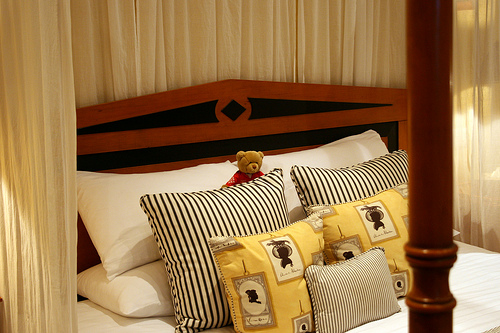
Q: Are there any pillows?
A: Yes, there is a pillow.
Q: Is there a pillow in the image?
A: Yes, there is a pillow.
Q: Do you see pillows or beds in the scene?
A: Yes, there is a pillow.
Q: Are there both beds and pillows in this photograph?
A: Yes, there are both a pillow and a bed.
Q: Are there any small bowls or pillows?
A: Yes, there is a small pillow.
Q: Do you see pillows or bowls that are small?
A: Yes, the pillow is small.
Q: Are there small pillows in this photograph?
A: Yes, there is a small pillow.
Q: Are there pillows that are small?
A: Yes, there is a small pillow.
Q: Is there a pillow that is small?
A: Yes, there is a pillow that is small.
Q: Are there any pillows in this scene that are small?
A: Yes, there is a pillow that is small.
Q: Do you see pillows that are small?
A: Yes, there is a pillow that is small.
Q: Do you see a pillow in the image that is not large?
A: Yes, there is a small pillow.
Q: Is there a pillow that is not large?
A: Yes, there is a small pillow.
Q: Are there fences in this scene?
A: No, there are no fences.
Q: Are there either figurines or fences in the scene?
A: No, there are no fences or figurines.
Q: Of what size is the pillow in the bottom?
A: The pillow is small.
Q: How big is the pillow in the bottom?
A: The pillow is small.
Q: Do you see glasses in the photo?
A: No, there are no glasses.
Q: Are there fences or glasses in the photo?
A: No, there are no glasses or fences.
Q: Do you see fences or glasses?
A: No, there are no glasses or fences.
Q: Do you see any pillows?
A: Yes, there is a pillow.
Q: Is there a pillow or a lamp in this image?
A: Yes, there is a pillow.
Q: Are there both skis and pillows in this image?
A: No, there is a pillow but no skis.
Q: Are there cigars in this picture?
A: No, there are no cigars.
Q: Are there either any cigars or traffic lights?
A: No, there are no cigars or traffic lights.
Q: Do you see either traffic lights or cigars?
A: No, there are no cigars or traffic lights.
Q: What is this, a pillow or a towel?
A: This is a pillow.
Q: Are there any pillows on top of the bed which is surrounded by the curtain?
A: Yes, there is a pillow on top of the bed.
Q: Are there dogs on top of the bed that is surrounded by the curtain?
A: No, there is a pillow on top of the bed.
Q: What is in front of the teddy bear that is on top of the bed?
A: The pillow is in front of the teddy bear.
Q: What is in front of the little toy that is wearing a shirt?
A: The pillow is in front of the teddy bear.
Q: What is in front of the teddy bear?
A: The pillow is in front of the teddy bear.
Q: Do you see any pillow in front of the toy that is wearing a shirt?
A: Yes, there is a pillow in front of the teddy bear.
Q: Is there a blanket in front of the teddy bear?
A: No, there is a pillow in front of the teddy bear.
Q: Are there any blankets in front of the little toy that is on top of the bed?
A: No, there is a pillow in front of the teddy bear.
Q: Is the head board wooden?
A: Yes, the head board is wooden.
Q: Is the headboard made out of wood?
A: Yes, the headboard is made of wood.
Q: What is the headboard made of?
A: The headboard is made of wood.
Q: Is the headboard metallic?
A: No, the headboard is wooden.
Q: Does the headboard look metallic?
A: No, the headboard is wooden.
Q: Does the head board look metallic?
A: No, the head board is wooden.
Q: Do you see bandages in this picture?
A: No, there are no bandages.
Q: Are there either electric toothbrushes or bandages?
A: No, there are no bandages or electric toothbrushes.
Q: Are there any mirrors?
A: No, there are no mirrors.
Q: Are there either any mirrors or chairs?
A: No, there are no mirrors or chairs.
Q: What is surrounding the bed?
A: The curtain is surrounding the bed.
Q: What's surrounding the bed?
A: The curtain is surrounding the bed.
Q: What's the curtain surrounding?
A: The curtain is surrounding the bed.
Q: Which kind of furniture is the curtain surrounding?
A: The curtain is surrounding the bed.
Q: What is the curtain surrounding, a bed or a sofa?
A: The curtain is surrounding a bed.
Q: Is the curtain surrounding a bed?
A: Yes, the curtain is surrounding a bed.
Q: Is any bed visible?
A: Yes, there is a bed.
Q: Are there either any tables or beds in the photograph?
A: Yes, there is a bed.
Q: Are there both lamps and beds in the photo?
A: No, there is a bed but no lamps.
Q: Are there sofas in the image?
A: No, there are no sofas.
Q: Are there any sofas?
A: No, there are no sofas.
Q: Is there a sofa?
A: No, there are no sofas.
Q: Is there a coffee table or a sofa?
A: No, there are no sofas or coffee tables.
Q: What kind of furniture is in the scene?
A: The furniture is a bed.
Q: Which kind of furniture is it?
A: The piece of furniture is a bed.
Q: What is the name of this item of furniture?
A: This is a bed.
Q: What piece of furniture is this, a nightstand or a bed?
A: This is a bed.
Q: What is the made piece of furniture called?
A: The piece of furniture is a bed.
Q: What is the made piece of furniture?
A: The piece of furniture is a bed.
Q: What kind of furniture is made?
A: The furniture is a bed.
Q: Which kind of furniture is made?
A: The furniture is a bed.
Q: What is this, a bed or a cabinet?
A: This is a bed.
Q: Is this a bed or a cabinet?
A: This is a bed.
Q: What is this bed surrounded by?
A: The bed is surrounded by the curtain.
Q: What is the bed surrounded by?
A: The bed is surrounded by the curtain.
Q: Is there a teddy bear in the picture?
A: Yes, there is a teddy bear.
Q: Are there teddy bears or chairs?
A: Yes, there is a teddy bear.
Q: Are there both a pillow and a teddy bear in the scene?
A: Yes, there are both a teddy bear and a pillow.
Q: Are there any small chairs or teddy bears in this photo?
A: Yes, there is a small teddy bear.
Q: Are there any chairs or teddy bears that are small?
A: Yes, the teddy bear is small.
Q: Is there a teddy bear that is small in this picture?
A: Yes, there is a small teddy bear.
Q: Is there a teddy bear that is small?
A: Yes, there is a teddy bear that is small.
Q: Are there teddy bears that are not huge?
A: Yes, there is a small teddy bear.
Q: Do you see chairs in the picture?
A: No, there are no chairs.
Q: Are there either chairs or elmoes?
A: No, there are no chairs or elmoes.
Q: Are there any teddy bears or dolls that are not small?
A: No, there is a teddy bear but it is small.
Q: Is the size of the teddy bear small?
A: Yes, the teddy bear is small.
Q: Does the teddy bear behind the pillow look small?
A: Yes, the teddy bear is small.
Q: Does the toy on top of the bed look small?
A: Yes, the teddy bear is small.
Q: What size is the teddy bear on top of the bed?
A: The teddy bear is small.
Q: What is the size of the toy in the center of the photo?
A: The teddy bear is small.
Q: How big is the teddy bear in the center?
A: The teddy bear is small.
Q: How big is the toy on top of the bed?
A: The teddy bear is small.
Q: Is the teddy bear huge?
A: No, the teddy bear is small.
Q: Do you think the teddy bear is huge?
A: No, the teddy bear is small.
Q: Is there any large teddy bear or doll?
A: No, there is a teddy bear but it is small.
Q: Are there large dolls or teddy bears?
A: No, there is a teddy bear but it is small.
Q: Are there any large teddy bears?
A: No, there is a teddy bear but it is small.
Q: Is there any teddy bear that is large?
A: No, there is a teddy bear but it is small.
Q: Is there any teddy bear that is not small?
A: No, there is a teddy bear but it is small.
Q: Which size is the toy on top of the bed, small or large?
A: The teddy bear is small.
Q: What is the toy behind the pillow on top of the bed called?
A: The toy is a teddy bear.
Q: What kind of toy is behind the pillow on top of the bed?
A: The toy is a teddy bear.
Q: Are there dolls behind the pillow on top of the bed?
A: No, there is a teddy bear behind the pillow.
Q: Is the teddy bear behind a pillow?
A: Yes, the teddy bear is behind a pillow.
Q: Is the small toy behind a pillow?
A: Yes, the teddy bear is behind a pillow.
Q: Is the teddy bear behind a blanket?
A: No, the teddy bear is behind a pillow.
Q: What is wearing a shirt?
A: The teddy bear is wearing a shirt.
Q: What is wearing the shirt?
A: The teddy bear is wearing a shirt.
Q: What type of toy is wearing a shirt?
A: The toy is a teddy bear.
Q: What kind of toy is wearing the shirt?
A: The toy is a teddy bear.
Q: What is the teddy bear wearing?
A: The teddy bear is wearing a shirt.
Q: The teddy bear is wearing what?
A: The teddy bear is wearing a shirt.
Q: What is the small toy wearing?
A: The teddy bear is wearing a shirt.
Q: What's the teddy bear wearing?
A: The teddy bear is wearing a shirt.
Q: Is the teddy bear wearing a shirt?
A: Yes, the teddy bear is wearing a shirt.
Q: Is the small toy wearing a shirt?
A: Yes, the teddy bear is wearing a shirt.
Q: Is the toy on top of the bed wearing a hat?
A: No, the teddy bear is wearing a shirt.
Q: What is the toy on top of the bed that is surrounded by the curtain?
A: The toy is a teddy bear.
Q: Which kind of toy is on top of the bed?
A: The toy is a teddy bear.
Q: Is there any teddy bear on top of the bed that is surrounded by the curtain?
A: Yes, there is a teddy bear on top of the bed.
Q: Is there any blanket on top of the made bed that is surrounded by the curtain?
A: No, there is a teddy bear on top of the bed.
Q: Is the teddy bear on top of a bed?
A: Yes, the teddy bear is on top of a bed.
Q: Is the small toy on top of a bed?
A: Yes, the teddy bear is on top of a bed.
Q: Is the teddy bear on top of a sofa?
A: No, the teddy bear is on top of a bed.